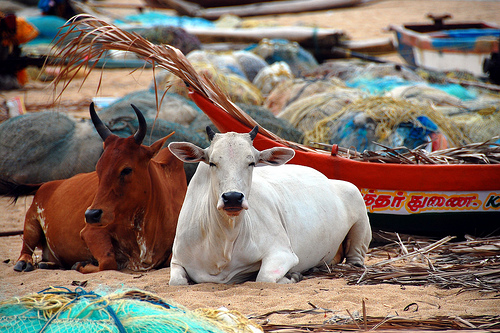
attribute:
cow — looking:
[167, 116, 396, 296]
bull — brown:
[16, 108, 171, 284]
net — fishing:
[0, 34, 498, 192]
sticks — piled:
[369, 227, 499, 322]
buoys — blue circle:
[0, 287, 225, 332]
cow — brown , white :
[13, 100, 187, 272]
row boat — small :
[378, 12, 499, 78]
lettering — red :
[352, 169, 487, 218]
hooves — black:
[0, 235, 116, 272]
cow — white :
[170, 128, 378, 275]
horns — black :
[197, 121, 263, 142]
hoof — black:
[12, 258, 32, 270]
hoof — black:
[70, 260, 91, 270]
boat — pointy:
[24, 6, 498, 261]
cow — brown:
[18, 126, 168, 286]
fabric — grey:
[29, 8, 209, 60]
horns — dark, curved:
[88, 98, 146, 147]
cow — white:
[164, 118, 372, 289]